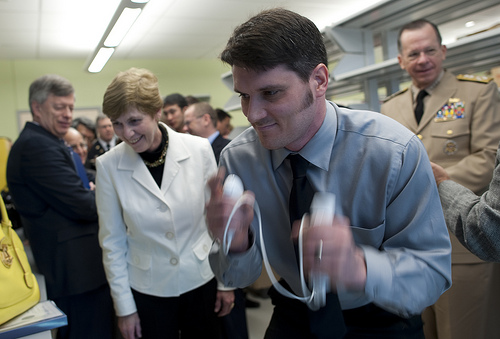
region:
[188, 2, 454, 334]
man holding controllers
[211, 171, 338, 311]
controllers are white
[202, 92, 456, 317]
man is wearing a blue shirt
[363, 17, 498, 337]
man is wearing a uniform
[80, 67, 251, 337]
woman is smiling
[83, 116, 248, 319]
woman is wearing a white jacket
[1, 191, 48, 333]
a yellow purse on a table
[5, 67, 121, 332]
man is looking down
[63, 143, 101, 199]
man is holding a folder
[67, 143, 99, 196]
folder is blue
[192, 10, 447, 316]
Man holding game controllers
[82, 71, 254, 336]
Woman is watching game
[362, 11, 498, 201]
Man is wearing uniform.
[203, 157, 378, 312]
Man is shaking his arms.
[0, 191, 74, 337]
Yellow purse on stand.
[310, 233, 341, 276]
Man is wearing ring.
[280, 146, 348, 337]
Man is wearing navy tie.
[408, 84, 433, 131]
Man is wearing black tie.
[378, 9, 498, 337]
Man is standing in background.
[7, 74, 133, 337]
Man is leaning on stand.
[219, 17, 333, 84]
the hair is black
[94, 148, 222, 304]
the top is white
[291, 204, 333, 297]
the wii remote is white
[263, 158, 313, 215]
the tie is black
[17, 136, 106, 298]
the blazer is black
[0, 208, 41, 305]
the hand bag is yellow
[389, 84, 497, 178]
the uniform is brown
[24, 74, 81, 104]
the hair is white and black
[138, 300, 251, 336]
the pants are black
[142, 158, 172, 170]
the necklace is silver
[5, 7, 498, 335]
People looking at something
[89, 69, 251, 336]
Woman has a white jacket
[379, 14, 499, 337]
Old man wearing a military uniform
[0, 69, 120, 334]
Man wearing black suit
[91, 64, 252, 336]
Woman is smiling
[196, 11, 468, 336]
Man holding a wired white device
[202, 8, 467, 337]
Man holding a blue shirt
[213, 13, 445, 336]
Man wears black pants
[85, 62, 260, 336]
Woman wear black skirt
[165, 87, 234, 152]
People talking behind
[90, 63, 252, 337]
a woman wearing a white blazer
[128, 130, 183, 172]
a gold chain necklace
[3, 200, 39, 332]
the corner of a bright yellow pocket book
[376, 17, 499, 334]
a man is wearing a tan military uniform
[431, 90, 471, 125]
many military pins on a jacket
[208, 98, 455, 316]
the crouching man is playing a wii game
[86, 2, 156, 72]
the overhead lights are turned on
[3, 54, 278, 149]
the back wall is pale green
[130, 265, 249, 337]
the woman is wearing black pants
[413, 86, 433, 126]
the man in uniform is wearing a black tie